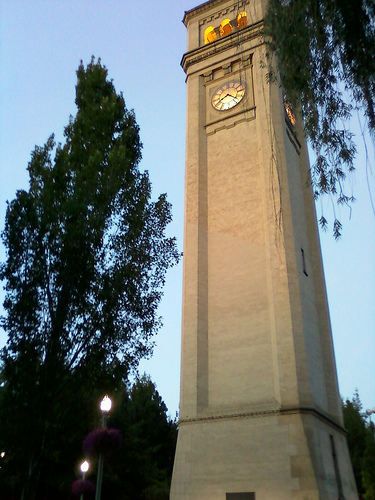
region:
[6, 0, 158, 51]
the sky is clear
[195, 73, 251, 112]
the clock on the tower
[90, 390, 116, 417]
the light below the tower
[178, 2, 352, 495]
the tower is brick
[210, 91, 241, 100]
hands on the clock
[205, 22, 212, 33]
light inside of the tower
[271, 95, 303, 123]
clock on the tower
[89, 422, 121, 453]
purple wreath on the pole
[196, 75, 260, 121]
the clock is illuminated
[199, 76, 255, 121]
the clock is illuminated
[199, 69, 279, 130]
the clock is illuminated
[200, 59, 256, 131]
the clock is illuminated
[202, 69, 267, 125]
the clock is illuminated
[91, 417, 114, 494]
the pole is green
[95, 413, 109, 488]
the pole is green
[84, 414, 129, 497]
the pole is green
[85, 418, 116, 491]
the pole is green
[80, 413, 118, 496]
the pole is green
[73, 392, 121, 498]
Street lights next to the tower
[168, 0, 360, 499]
Stone clock tower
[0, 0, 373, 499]
Trees next to the stone clock tower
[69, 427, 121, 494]
Burgundy decorations on the light posts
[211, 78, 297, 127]
Illuminated clock faces on the stone tower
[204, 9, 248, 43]
Illuminated stone arches on the tower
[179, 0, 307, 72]
Stone decorations going around the tower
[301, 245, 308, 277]
Window in the clock tower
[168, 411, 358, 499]
Inter laid stone bricks in the tower foundation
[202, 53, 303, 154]
Stone decorations around the clock faces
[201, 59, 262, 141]
The clock on the tower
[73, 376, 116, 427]
Light on top of the post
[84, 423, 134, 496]
Post is made of metal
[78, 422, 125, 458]
Flowers hanging on the pole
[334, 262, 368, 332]
The sky is blue with no clouds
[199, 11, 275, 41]
Top of the tower is lighted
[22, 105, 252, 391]
Trees behind the street lights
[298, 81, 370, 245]
Tree leaves hanging down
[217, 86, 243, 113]
Clock hands on the clock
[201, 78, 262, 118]
Clock on a large tower.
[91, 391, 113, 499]
Light on the pole.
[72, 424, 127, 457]
Flowers surrounding a pole.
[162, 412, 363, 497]
Stone foundation of tower.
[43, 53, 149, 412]
Large tree beside tower.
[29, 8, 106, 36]
A clear blue sky.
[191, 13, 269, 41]
Window at the top of a tower.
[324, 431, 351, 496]
Door to the top of a tower.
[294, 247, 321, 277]
Window in the side of tower.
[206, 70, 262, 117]
this is a clock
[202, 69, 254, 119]
the clock is lit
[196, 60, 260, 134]
the clock is round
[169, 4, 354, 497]
this is a clock tower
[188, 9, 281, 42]
there is an orange light coming from the tower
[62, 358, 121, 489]
these are lamp posts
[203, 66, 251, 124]
the clock is lit up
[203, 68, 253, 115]
the clock is illuminated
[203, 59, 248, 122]
the clock has Roman numerals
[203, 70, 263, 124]
clock on tall tower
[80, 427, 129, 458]
purple flowers on light pole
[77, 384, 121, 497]
light poles wit purple flowers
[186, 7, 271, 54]
open section at top of clock tower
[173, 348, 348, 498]
large stone base of clock tower